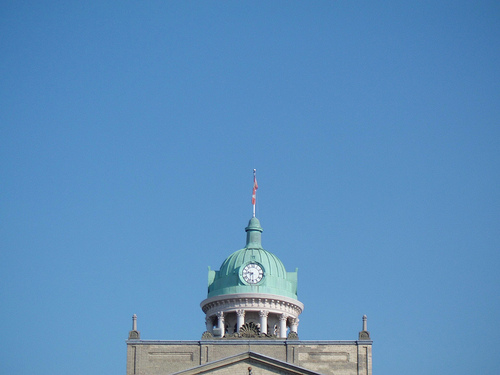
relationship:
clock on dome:
[242, 262, 268, 287] [214, 245, 295, 297]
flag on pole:
[251, 176, 260, 196] [252, 163, 261, 230]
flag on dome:
[251, 176, 260, 196] [214, 245, 295, 297]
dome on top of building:
[214, 245, 295, 297] [126, 335, 367, 374]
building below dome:
[126, 335, 367, 374] [214, 245, 295, 297]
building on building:
[123, 168, 376, 375] [126, 335, 367, 374]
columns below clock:
[215, 313, 296, 334] [242, 262, 268, 287]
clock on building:
[242, 262, 268, 287] [123, 168, 376, 375]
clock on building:
[242, 262, 268, 287] [126, 335, 367, 374]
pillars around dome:
[217, 311, 291, 335] [214, 245, 295, 297]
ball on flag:
[252, 166, 258, 174] [251, 176, 260, 196]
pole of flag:
[252, 163, 261, 230] [251, 176, 260, 196]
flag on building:
[251, 176, 260, 196] [126, 335, 367, 374]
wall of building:
[130, 344, 361, 375] [126, 335, 367, 374]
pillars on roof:
[217, 311, 291, 335] [217, 231, 289, 300]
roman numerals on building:
[243, 267, 265, 286] [126, 335, 367, 374]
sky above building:
[10, 6, 500, 367] [126, 335, 367, 374]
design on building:
[243, 326, 261, 343] [126, 335, 367, 374]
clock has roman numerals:
[242, 262, 268, 287] [243, 267, 265, 286]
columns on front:
[215, 313, 296, 334] [121, 160, 381, 371]